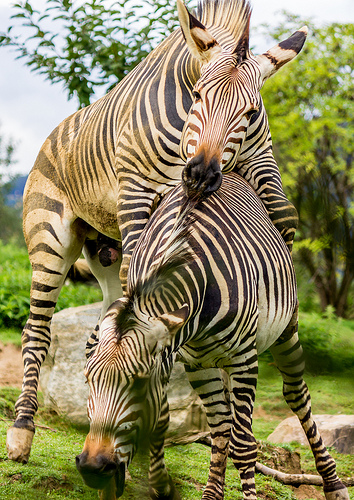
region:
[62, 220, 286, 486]
there are two zebras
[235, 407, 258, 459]
stripes on the zebra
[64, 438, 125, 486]
nose of the zebra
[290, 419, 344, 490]
leg of the zebra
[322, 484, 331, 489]
hoof of the zebra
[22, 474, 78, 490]
dirt in the grass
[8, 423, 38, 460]
hoof of the horse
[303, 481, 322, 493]
dirt patch in grass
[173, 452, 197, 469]
the grass is short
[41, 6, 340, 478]
two zebras mating with each other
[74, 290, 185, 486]
the head of an adult zebra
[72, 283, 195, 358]
the ears of an adult zebra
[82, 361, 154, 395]
the eyes of an adult zebra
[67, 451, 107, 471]
the nose of an adult zebra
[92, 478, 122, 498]
the tongue of an adult zebra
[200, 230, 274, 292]
the stripes of an adult zebra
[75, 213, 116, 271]
the penis of an adult zebra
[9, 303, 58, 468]
the leg of an adult zebra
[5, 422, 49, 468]
the hoof of an adult zebra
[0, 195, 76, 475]
Leg of a zebra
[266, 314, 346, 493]
Leg of a zebra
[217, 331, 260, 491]
Leg of a zebra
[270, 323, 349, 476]
Leg of a giraffeLeg of a zebra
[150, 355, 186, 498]
Leg of a zebra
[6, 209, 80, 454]
Leg of a zebra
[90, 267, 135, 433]
Leg of a zebra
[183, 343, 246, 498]
Leg of a zebra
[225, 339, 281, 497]
Leg of a zebra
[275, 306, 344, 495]
Leg of a zebra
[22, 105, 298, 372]
A zebra on top of a zebra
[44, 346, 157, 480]
A zebra looking down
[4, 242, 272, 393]
A animal with black and white stripes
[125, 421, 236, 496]
Green grass on the ground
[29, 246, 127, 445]
A large rock behind the zebra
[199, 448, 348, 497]
A tree lamb on the ground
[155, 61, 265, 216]
Zebras head on the back of the zebras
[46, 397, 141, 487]
Black part of a zebras nose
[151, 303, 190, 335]
An ear on a zebra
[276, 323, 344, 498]
A back leg on a zebra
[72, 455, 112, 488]
A nose on a zebra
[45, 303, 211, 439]
A large rock behind zebras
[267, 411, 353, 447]
A rock behind zebras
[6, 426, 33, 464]
A hoof on a zebra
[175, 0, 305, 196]
A zebra's head on another zebra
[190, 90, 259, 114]
Eyes on a zebra's face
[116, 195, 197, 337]
A mane on a zebra's neck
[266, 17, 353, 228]
green leaves on the tree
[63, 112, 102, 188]
dirt on the fur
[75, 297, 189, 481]
the head of a zebra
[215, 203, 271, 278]
the stripes are black and white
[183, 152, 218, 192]
the nose has black fur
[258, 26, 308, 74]
the ear is black and white